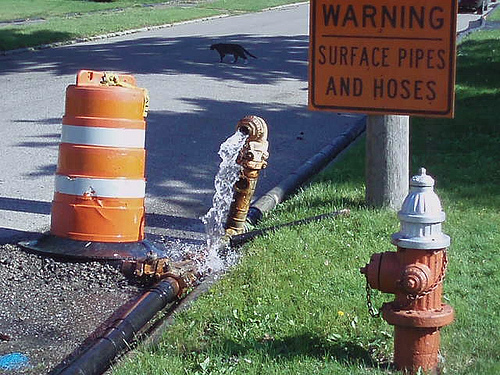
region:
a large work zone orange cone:
[37, 65, 161, 257]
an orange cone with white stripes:
[29, 65, 166, 261]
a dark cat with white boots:
[209, 40, 256, 61]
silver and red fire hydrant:
[359, 166, 457, 370]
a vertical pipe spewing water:
[210, 112, 267, 226]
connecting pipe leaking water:
[124, 240, 210, 297]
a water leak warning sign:
[308, 2, 458, 118]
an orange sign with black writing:
[307, 2, 457, 119]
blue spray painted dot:
[3, 345, 25, 372]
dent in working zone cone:
[75, 180, 108, 212]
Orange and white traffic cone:
[22, 67, 162, 259]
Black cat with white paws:
[208, 40, 258, 68]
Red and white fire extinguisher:
[360, 165, 460, 374]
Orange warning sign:
[305, 0, 458, 119]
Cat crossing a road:
[205, 38, 257, 68]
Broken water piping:
[42, 114, 267, 374]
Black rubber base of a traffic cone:
[17, 230, 167, 262]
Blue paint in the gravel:
[0, 346, 32, 373]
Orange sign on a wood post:
[305, 1, 457, 212]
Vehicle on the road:
[456, 0, 491, 15]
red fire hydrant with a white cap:
[364, 168, 454, 356]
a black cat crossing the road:
[211, 40, 256, 64]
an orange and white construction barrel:
[30, 67, 164, 262]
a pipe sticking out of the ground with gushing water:
[211, 117, 261, 234]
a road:
[7, 2, 488, 254]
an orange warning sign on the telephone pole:
[309, 4, 454, 111]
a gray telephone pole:
[363, 111, 413, 203]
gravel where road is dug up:
[7, 248, 148, 372]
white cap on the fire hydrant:
[390, 170, 452, 246]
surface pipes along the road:
[70, 110, 365, 372]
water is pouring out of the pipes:
[157, 105, 280, 282]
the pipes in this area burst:
[134, 105, 299, 306]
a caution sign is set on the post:
[313, 3, 457, 140]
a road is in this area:
[0, 6, 315, 256]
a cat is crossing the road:
[194, 25, 263, 82]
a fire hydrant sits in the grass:
[347, 164, 463, 369]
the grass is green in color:
[179, 175, 499, 362]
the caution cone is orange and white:
[13, 55, 180, 294]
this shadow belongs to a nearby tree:
[11, 19, 490, 131]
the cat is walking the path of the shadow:
[184, 29, 257, 77]